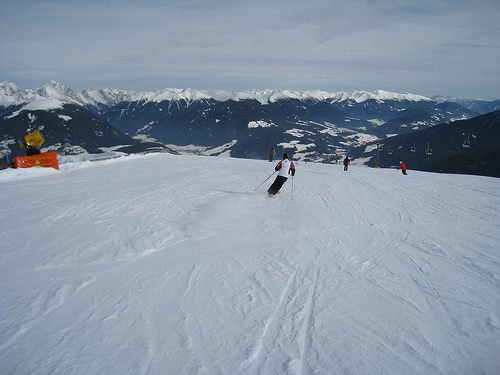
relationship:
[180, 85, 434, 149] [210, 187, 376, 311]
mountain with snow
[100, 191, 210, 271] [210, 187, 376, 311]
mark on snow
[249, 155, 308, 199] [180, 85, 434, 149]
skier on mountain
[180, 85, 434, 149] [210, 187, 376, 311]
mountain has snow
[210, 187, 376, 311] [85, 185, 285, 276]
snow on ground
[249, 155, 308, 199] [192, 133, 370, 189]
skier on hill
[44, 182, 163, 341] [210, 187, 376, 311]
tracks in snow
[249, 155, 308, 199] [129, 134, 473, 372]
skier on hill